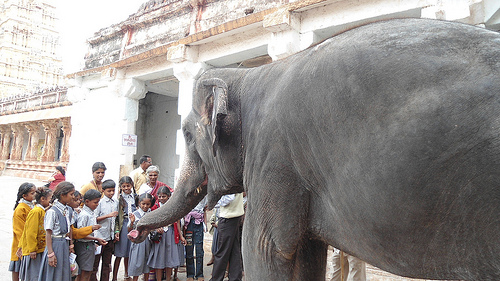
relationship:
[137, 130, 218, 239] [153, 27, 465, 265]
trunk of elephant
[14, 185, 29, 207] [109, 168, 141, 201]
pigtails on girl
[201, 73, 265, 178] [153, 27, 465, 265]
ear of elephant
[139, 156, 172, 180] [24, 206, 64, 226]
woman in yellow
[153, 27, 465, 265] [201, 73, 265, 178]
elephant has ear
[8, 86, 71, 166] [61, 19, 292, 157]
columns on building